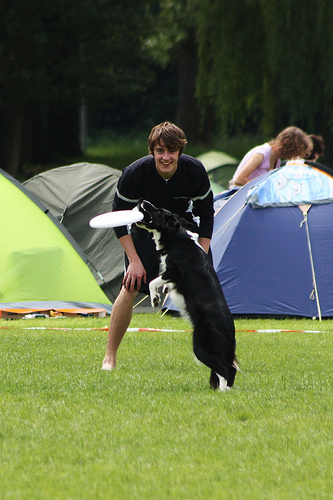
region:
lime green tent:
[0, 157, 122, 347]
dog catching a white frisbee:
[93, 200, 250, 398]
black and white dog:
[132, 197, 250, 398]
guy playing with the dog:
[80, 103, 251, 394]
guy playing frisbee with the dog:
[76, 108, 252, 400]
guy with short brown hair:
[82, 114, 248, 398]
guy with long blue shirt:
[87, 110, 250, 398]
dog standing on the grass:
[85, 195, 264, 405]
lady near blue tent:
[223, 106, 330, 320]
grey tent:
[26, 133, 148, 329]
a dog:
[140, 216, 244, 390]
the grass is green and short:
[49, 394, 231, 482]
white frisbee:
[93, 214, 144, 227]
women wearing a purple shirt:
[226, 138, 270, 173]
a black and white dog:
[144, 264, 226, 330]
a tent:
[11, 225, 66, 277]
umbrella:
[271, 179, 320, 199]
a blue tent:
[239, 228, 296, 286]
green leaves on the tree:
[200, 50, 281, 95]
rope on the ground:
[270, 321, 304, 337]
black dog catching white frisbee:
[87, 198, 240, 394]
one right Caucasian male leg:
[95, 287, 139, 372]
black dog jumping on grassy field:
[138, 196, 239, 393]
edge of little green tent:
[1, 156, 115, 322]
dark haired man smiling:
[144, 116, 187, 179]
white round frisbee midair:
[86, 200, 143, 233]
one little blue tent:
[215, 150, 331, 322]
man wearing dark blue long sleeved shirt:
[107, 118, 214, 206]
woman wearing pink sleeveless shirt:
[223, 123, 313, 185]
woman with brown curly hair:
[272, 126, 313, 161]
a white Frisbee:
[88, 208, 146, 231]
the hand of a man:
[119, 262, 150, 292]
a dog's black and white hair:
[130, 198, 239, 389]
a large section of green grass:
[0, 314, 332, 498]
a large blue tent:
[155, 157, 331, 323]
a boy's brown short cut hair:
[144, 121, 186, 151]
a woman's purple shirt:
[230, 142, 279, 191]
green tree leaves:
[139, 0, 183, 64]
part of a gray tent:
[23, 161, 128, 298]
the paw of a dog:
[150, 293, 161, 310]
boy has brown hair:
[135, 117, 211, 156]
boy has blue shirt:
[123, 154, 216, 232]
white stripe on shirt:
[110, 180, 249, 214]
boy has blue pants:
[106, 236, 167, 288]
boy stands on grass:
[82, 108, 248, 410]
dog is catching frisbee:
[86, 196, 138, 245]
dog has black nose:
[135, 201, 164, 234]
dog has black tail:
[203, 357, 241, 410]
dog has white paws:
[118, 266, 184, 319]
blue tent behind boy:
[226, 146, 330, 317]